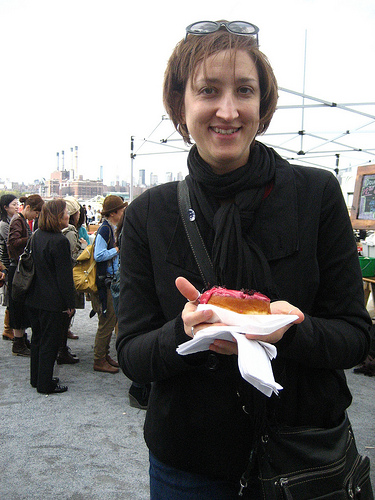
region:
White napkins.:
[180, 304, 296, 392]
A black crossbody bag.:
[177, 167, 371, 492]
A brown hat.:
[96, 194, 127, 215]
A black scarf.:
[187, 134, 281, 300]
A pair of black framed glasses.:
[185, 21, 264, 49]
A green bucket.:
[362, 256, 374, 275]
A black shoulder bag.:
[12, 234, 40, 295]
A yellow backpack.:
[73, 231, 103, 292]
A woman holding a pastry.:
[110, 19, 371, 484]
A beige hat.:
[63, 197, 83, 214]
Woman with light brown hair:
[161, 17, 280, 165]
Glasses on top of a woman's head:
[180, 19, 262, 55]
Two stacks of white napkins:
[172, 305, 303, 399]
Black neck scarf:
[183, 140, 280, 286]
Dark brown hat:
[100, 194, 128, 218]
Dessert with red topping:
[199, 283, 275, 317]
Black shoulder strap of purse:
[173, 177, 222, 286]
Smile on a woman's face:
[206, 121, 244, 142]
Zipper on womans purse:
[274, 455, 353, 489]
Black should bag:
[10, 226, 37, 297]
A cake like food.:
[196, 283, 272, 318]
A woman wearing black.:
[115, 19, 373, 499]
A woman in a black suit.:
[13, 197, 75, 393]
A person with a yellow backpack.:
[73, 194, 128, 374]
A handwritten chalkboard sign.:
[349, 165, 374, 228]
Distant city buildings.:
[2, 143, 185, 201]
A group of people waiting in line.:
[0, 192, 128, 392]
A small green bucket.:
[358, 254, 374, 276]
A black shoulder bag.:
[175, 179, 373, 498]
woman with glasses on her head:
[173, 16, 264, 54]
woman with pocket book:
[235, 425, 370, 496]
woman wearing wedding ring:
[178, 322, 208, 347]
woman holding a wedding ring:
[181, 275, 290, 351]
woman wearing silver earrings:
[164, 114, 197, 145]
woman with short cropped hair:
[155, 32, 265, 132]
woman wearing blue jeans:
[125, 444, 173, 491]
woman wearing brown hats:
[100, 193, 127, 219]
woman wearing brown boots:
[90, 344, 127, 385]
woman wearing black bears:
[27, 293, 88, 410]